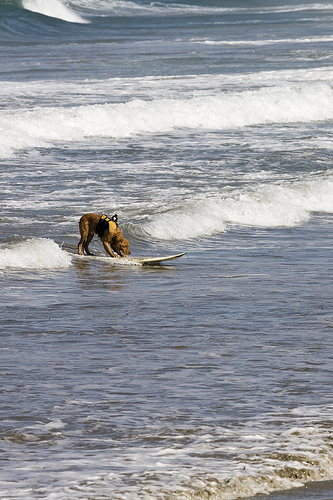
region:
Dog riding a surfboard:
[71, 208, 135, 266]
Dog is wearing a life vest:
[99, 208, 129, 253]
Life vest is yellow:
[100, 209, 122, 245]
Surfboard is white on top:
[61, 240, 200, 274]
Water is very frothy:
[136, 423, 329, 493]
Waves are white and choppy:
[141, 192, 328, 245]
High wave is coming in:
[11, 0, 116, 47]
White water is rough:
[76, 71, 248, 144]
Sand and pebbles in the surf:
[273, 446, 331, 493]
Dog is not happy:
[71, 207, 142, 269]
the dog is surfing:
[33, 185, 209, 322]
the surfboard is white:
[62, 218, 198, 297]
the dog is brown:
[38, 200, 147, 292]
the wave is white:
[6, 69, 327, 154]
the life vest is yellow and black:
[76, 201, 146, 275]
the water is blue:
[5, 3, 331, 121]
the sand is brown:
[154, 452, 331, 499]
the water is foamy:
[7, 406, 315, 498]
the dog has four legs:
[73, 227, 127, 267]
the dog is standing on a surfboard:
[57, 204, 217, 304]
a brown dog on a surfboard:
[71, 210, 188, 278]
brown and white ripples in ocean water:
[16, 389, 309, 493]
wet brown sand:
[272, 492, 327, 497]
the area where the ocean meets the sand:
[140, 457, 330, 495]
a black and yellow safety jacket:
[94, 214, 118, 235]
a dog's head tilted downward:
[115, 238, 132, 256]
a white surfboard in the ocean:
[42, 240, 192, 270]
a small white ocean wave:
[127, 185, 323, 237]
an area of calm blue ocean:
[19, 20, 209, 58]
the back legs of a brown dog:
[75, 225, 92, 254]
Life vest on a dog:
[95, 213, 120, 240]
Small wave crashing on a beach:
[197, 467, 306, 491]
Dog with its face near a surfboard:
[116, 236, 131, 253]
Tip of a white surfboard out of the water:
[137, 251, 191, 268]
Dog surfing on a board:
[68, 209, 187, 264]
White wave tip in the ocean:
[10, 92, 243, 135]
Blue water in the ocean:
[112, 20, 208, 40]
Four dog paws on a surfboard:
[74, 241, 130, 261]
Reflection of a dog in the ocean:
[73, 259, 136, 294]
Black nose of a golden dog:
[128, 250, 130, 254]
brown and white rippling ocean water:
[38, 436, 324, 490]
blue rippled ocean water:
[43, 295, 308, 375]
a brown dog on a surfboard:
[74, 209, 137, 256]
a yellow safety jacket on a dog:
[97, 210, 123, 243]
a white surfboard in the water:
[76, 250, 188, 269]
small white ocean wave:
[161, 192, 332, 226]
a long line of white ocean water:
[2, 88, 331, 131]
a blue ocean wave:
[4, 3, 57, 42]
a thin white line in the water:
[203, 38, 328, 46]